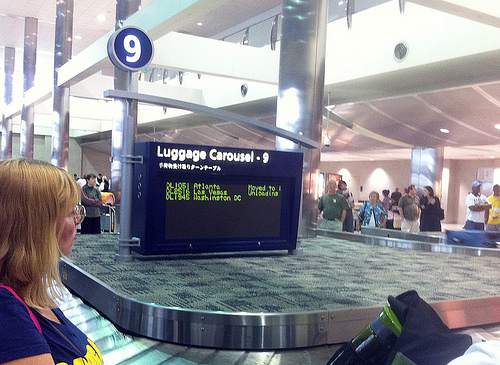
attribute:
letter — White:
[152, 144, 167, 161]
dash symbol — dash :
[256, 153, 261, 160]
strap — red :
[1, 281, 48, 336]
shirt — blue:
[356, 200, 387, 225]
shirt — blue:
[1, 284, 103, 364]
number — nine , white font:
[261, 147, 271, 163]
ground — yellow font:
[343, 82, 365, 100]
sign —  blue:
[102, 13, 202, 90]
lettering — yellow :
[82, 337, 104, 363]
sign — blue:
[89, 122, 320, 267]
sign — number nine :
[104, 18, 155, 78]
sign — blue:
[132, 140, 299, 221]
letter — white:
[192, 149, 199, 162]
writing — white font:
[154, 143, 259, 165]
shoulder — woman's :
[0, 262, 28, 344]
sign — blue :
[136, 137, 307, 248]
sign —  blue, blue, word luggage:
[137, 140, 303, 260]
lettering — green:
[160, 182, 286, 201]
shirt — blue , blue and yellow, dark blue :
[4, 280, 104, 362]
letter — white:
[178, 148, 186, 164]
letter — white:
[186, 148, 194, 161]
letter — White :
[164, 139, 262, 164]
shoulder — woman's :
[3, 287, 69, 362]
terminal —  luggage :
[4, 51, 483, 356]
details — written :
[154, 180, 296, 219]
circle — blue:
[110, 27, 151, 69]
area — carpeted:
[67, 230, 498, 317]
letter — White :
[180, 140, 197, 149]